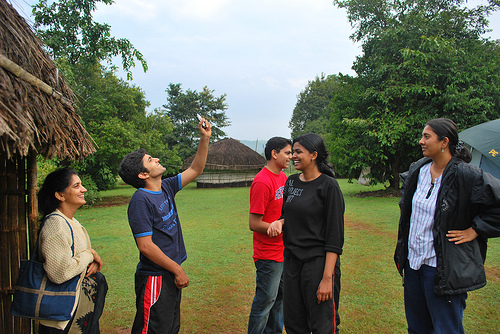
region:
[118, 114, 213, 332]
A young man holding up a camera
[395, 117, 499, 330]
A woman in a black coat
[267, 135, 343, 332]
A woman in black smiling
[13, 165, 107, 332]
A woman in brown smiling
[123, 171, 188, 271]
Blue shirt being worn by a male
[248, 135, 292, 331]
A man in a red shirt smiling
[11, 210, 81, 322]
A blue bag hanging off of a woman's shoulder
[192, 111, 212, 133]
A cellular phone being lifted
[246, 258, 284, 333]
Blue jeans on a man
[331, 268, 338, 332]
Stripe on the side of a woman's pants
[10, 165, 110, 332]
Woman carrying blue bag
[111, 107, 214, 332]
Man in blue shirt and black pants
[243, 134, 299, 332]
Man in red shirt and blue jeans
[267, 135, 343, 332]
Long haired woman wearing black clothes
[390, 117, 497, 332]
Woman wearing unzipped black jacket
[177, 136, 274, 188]
Circular shaped hut with grass roof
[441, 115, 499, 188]
Green tent with yellow letters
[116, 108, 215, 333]
Man taking selfie with phone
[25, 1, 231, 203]
Three large green trees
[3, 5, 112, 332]
Woman standing beside straw and wood hut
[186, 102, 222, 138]
phone in man's hand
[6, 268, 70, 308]
gray cross on bag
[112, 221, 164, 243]
blue stripe around shirt sleeve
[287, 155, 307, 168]
smile on woman's face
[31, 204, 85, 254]
blue strap around shoulders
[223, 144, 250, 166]
thatch roof on house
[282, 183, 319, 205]
logo on black shirt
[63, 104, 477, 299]
people standing on grass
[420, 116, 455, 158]
the head of a lady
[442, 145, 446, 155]
an earing on the ear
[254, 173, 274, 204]
a red T-shirt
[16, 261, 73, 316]
a lady's bag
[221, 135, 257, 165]
a grass thatched hut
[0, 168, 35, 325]
wooden poles on the hut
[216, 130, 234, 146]
the tip of a hut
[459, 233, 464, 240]
a ring on the finger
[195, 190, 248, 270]
green grass on the ground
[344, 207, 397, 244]
a foot path on the ground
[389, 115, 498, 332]
a woman standing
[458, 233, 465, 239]
a ring the woman is wearing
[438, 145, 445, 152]
an earing the woman is wearing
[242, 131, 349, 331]
a guy and a woman standing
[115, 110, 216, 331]
a guy standing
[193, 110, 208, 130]
a cellphone the guy is holding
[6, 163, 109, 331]
a woman standing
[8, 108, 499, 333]
people standing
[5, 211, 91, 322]
a shoulder bag the woman is carrying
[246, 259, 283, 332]
jeans the person is wearing